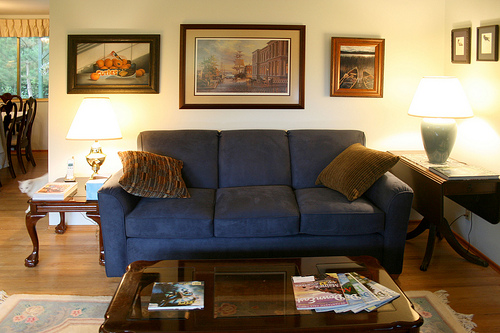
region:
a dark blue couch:
[104, 130, 410, 273]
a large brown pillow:
[311, 142, 399, 202]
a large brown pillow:
[117, 147, 187, 199]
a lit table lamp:
[63, 95, 125, 179]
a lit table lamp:
[405, 76, 474, 166]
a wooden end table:
[16, 170, 115, 270]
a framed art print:
[67, 32, 161, 94]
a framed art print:
[178, 22, 303, 109]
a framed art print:
[329, 35, 383, 98]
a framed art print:
[449, 23, 471, 65]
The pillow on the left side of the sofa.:
[126, 132, 199, 194]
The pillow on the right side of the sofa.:
[306, 132, 400, 209]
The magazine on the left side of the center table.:
[147, 273, 202, 310]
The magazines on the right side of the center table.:
[287, 270, 398, 315]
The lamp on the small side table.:
[67, 93, 126, 180]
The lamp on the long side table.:
[407, 71, 479, 169]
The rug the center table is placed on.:
[8, 286, 458, 329]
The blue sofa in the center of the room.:
[86, 113, 414, 275]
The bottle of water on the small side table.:
[65, 148, 77, 178]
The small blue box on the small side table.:
[80, 173, 110, 196]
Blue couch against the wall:
[110, 125, 471, 256]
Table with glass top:
[72, 246, 464, 331]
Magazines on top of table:
[277, 253, 437, 330]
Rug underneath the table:
[1, 285, 71, 326]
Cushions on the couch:
[166, 177, 363, 247]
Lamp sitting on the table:
[397, 62, 485, 159]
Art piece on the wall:
[162, 3, 317, 124]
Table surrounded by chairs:
[3, 83, 46, 187]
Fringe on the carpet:
[420, 293, 460, 325]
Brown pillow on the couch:
[307, 118, 397, 204]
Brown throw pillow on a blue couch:
[317, 143, 399, 203]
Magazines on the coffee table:
[290, 270, 396, 311]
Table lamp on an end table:
[406, 75, 471, 165]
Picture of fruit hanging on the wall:
[66, 32, 157, 92]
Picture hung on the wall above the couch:
[180, 21, 302, 106]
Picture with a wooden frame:
[330, 35, 381, 95]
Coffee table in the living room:
[101, 260, 422, 330]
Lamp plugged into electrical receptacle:
[461, 207, 467, 218]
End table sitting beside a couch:
[22, 173, 104, 263]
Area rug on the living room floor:
[0, 290, 470, 331]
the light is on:
[68, 96, 118, 149]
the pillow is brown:
[326, 142, 398, 192]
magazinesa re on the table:
[301, 247, 401, 331]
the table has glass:
[114, 248, 420, 330]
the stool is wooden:
[30, 174, 112, 270]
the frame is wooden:
[325, 28, 396, 115]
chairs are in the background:
[6, 87, 56, 181]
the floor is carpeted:
[12, 284, 63, 331]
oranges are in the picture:
[92, 53, 151, 95]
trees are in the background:
[5, 47, 50, 99]